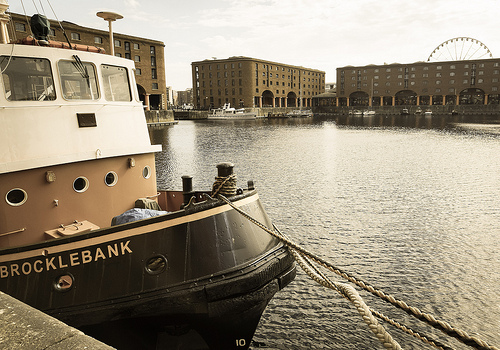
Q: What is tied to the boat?
A: A rope.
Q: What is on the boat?
A: Glass windows.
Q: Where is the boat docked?
A: Next to the dock.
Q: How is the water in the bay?
A: Calm.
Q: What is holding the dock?
A: Ropes.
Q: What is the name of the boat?
A: Brocklebank.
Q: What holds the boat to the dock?
A: Ropes.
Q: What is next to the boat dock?
A: Building.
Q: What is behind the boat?
A: Building with concrete base.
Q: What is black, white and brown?
A: Boat.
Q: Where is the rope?
A: Attached to boat.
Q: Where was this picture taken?
A: Outside at a dock.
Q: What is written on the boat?
A: Brocklebank.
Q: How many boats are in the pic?
A: 1.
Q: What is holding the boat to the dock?
A: Ropes.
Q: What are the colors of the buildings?
A: Tan.